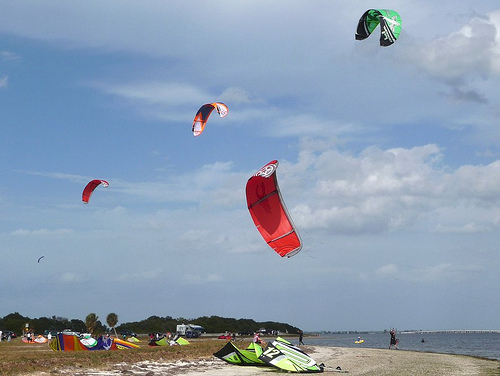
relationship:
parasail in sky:
[243, 154, 321, 275] [4, 1, 498, 335]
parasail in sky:
[77, 159, 111, 205] [4, 1, 498, 335]